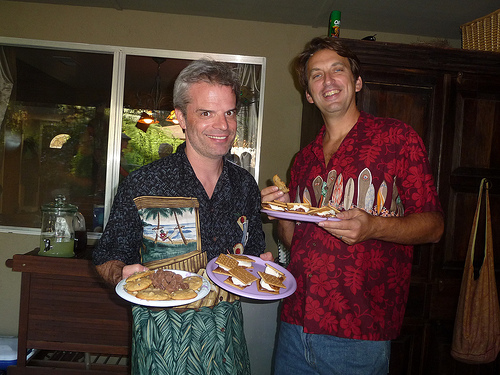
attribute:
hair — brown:
[292, 39, 356, 85]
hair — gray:
[162, 48, 249, 145]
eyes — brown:
[198, 106, 237, 120]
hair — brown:
[290, 31, 439, 272]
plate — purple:
[235, 252, 311, 293]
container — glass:
[34, 191, 82, 259]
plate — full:
[277, 190, 334, 252]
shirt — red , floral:
[282, 120, 442, 348]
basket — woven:
[457, 9, 497, 49]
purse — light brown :
[447, 172, 498, 355]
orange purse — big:
[461, 184, 496, 367]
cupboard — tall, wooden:
[298, 39, 497, 373]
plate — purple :
[208, 249, 298, 305]